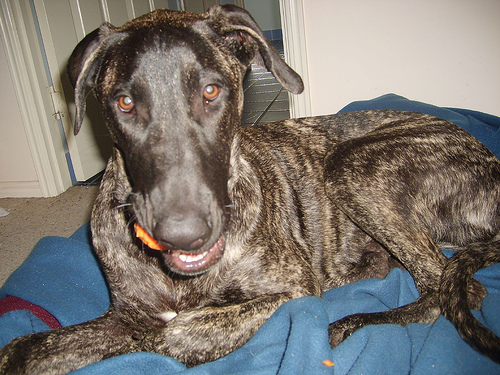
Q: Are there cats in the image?
A: No, there are no cats.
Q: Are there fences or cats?
A: No, there are no cats or fences.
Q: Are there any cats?
A: No, there are no cats.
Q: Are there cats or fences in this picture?
A: No, there are no cats or fences.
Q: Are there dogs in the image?
A: Yes, there is a dog.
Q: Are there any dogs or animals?
A: Yes, there is a dog.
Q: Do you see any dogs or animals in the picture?
A: Yes, there is a dog.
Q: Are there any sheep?
A: No, there are no sheep.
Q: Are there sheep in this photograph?
A: No, there are no sheep.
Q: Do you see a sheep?
A: No, there is no sheep.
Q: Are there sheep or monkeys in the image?
A: No, there are no sheep or monkeys.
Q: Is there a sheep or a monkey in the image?
A: No, there are no sheep or monkeys.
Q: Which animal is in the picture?
A: The animal is a dog.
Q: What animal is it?
A: The animal is a dog.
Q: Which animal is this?
A: This is a dog.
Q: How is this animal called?
A: This is a dog.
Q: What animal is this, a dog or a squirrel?
A: This is a dog.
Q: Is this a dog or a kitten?
A: This is a dog.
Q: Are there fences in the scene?
A: No, there are no fences.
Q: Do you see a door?
A: Yes, there is a door.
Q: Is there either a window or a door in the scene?
A: Yes, there is a door.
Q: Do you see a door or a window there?
A: Yes, there is a door.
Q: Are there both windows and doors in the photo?
A: No, there is a door but no windows.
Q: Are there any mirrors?
A: No, there are no mirrors.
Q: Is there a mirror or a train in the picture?
A: No, there are no mirrors or trains.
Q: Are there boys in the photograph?
A: No, there are no boys.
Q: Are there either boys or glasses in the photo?
A: No, there are no boys or glasses.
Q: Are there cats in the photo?
A: No, there are no cats.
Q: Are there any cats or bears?
A: No, there are no cats or bears.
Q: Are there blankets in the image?
A: Yes, there is a blanket.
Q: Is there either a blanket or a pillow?
A: Yes, there is a blanket.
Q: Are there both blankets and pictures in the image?
A: No, there is a blanket but no pictures.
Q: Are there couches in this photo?
A: No, there are no couches.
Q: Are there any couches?
A: No, there are no couches.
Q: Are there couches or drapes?
A: No, there are no couches or drapes.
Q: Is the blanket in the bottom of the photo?
A: Yes, the blanket is in the bottom of the image.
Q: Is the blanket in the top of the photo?
A: No, the blanket is in the bottom of the image.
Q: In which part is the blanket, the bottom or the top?
A: The blanket is in the bottom of the image.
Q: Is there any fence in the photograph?
A: No, there are no fences.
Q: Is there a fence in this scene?
A: No, there are no fences.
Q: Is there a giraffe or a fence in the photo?
A: No, there are no fences or giraffes.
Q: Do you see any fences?
A: No, there are no fences.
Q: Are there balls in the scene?
A: Yes, there is a ball.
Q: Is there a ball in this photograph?
A: Yes, there is a ball.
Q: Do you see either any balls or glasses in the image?
A: Yes, there is a ball.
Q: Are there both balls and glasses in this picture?
A: No, there is a ball but no glasses.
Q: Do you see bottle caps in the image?
A: No, there are no bottle caps.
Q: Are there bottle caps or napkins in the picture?
A: No, there are no bottle caps or napkins.